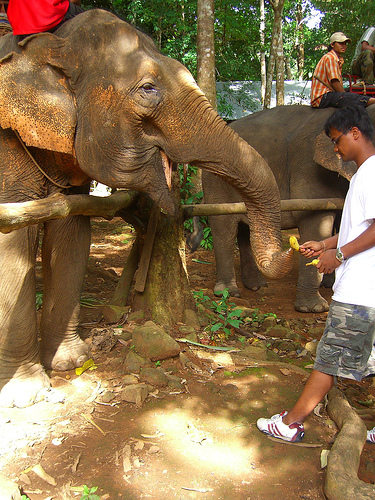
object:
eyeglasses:
[332, 127, 351, 145]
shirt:
[330, 154, 375, 309]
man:
[256, 108, 375, 444]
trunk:
[166, 84, 295, 281]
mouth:
[160, 147, 173, 216]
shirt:
[310, 49, 343, 108]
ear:
[0, 33, 77, 156]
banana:
[289, 235, 299, 251]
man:
[310, 32, 374, 109]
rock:
[132, 321, 180, 362]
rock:
[123, 350, 154, 373]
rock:
[140, 365, 168, 389]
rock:
[121, 382, 148, 406]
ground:
[2, 213, 375, 500]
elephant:
[0, 7, 294, 408]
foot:
[294, 292, 329, 312]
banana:
[305, 259, 319, 267]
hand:
[299, 240, 323, 259]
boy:
[256, 104, 375, 442]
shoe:
[256, 411, 304, 443]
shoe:
[367, 427, 375, 443]